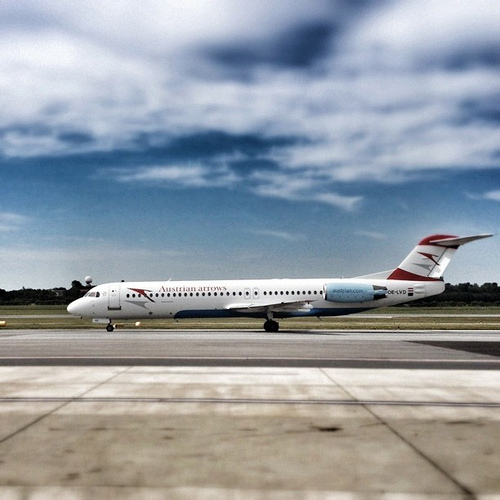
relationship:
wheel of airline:
[253, 310, 278, 329] [67, 234, 492, 334]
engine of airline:
[330, 276, 395, 305] [67, 234, 492, 334]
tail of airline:
[409, 210, 473, 283] [67, 234, 492, 334]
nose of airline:
[61, 285, 113, 329] [67, 234, 492, 334]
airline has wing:
[67, 234, 492, 334] [225, 293, 349, 351]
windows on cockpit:
[91, 286, 108, 305] [69, 276, 145, 323]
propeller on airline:
[307, 268, 348, 296] [67, 234, 492, 334]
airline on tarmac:
[67, 234, 492, 334] [39, 319, 455, 461]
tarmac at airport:
[39, 319, 455, 461] [64, 129, 477, 397]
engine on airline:
[330, 276, 395, 305] [67, 234, 492, 334]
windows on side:
[156, 261, 290, 315] [151, 228, 324, 376]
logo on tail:
[363, 254, 460, 290] [409, 210, 473, 283]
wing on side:
[225, 293, 349, 351] [151, 228, 324, 376]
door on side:
[99, 285, 136, 310] [151, 228, 324, 376]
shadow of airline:
[177, 312, 348, 345] [67, 234, 492, 334]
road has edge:
[360, 348, 482, 383] [421, 322, 485, 344]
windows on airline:
[91, 286, 108, 305] [67, 234, 492, 334]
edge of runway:
[421, 322, 485, 344] [73, 315, 493, 398]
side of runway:
[151, 228, 324, 376] [73, 315, 493, 398]